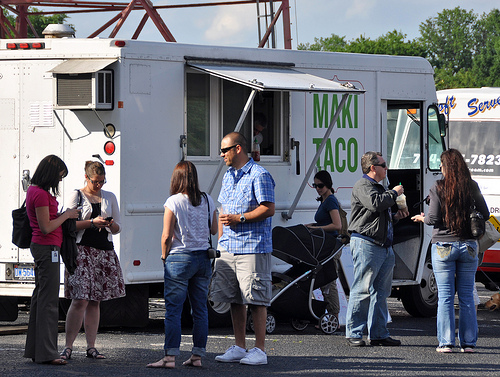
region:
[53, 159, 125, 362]
woman wearing white cardigan standing and looking at her cell phone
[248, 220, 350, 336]
black baby stroller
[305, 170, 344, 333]
woman wearing black t-shirt and sunglasses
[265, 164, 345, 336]
woman standing looking at the baby stroller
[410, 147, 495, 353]
long haired woman in jeans standing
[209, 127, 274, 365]
guy in blue shirt and khaki shorts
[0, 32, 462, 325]
white food truck selling tacos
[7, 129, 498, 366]
bunch of people standing in front of the food truck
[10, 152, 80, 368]
woman in pink shirt carrying a purse and looking at her cell phone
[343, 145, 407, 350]
guy in jeans and green jacket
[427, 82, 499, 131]
a truck says soft server.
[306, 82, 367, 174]
a big white truck says Maki Taco.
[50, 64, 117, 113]
a small air conditioner.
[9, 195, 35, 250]
a woman is wearing a black back pack.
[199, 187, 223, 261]
a woman is holding a camera on her shoulder.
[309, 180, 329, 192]
a woman is wearing glasses.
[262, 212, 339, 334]
a woman is pushing a baby stroller.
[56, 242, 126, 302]
a woman is wearing a flowered skirt.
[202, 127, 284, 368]
a guy wearing a blue shirt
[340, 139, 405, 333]
a guy wearing a gray shirt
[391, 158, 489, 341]
a girl wearing some blue jeans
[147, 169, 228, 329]
a girl wearing a white shirt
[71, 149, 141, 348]
a girl wearing a skirt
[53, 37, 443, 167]
a truck that sells tacos to people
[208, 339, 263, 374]
a pair of white shoes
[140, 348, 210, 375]
a pair of brown sandals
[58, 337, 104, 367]
a pair of blue sandals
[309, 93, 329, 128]
letter on white truck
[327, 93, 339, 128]
letter on white truck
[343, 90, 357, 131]
letter on white truck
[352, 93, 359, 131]
letter on white truck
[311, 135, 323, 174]
letter on white truck